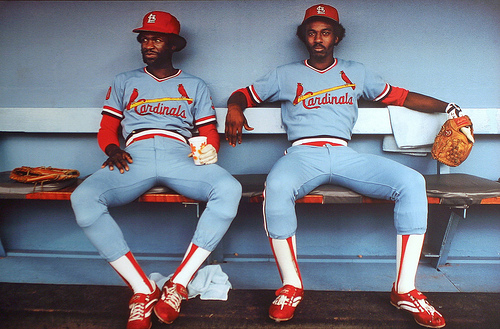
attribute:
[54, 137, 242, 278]
pants — blue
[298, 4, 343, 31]
hat — red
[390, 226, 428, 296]
red sock — white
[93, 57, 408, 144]
shirts — men's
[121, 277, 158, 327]
shoes — white, red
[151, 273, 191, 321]
shoes — white, red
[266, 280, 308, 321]
shoes — white, red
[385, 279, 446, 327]
shoes — white, red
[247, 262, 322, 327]
foot — right foot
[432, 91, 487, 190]
glove — light brown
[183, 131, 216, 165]
cup — white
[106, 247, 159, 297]
sock — red, white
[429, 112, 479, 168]
mitt — baseball mitt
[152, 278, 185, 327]
shoe — red, white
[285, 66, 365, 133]
logo — St. Louis Cardinals club's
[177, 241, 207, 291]
sock — white, red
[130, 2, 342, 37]
hats — men's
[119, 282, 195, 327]
shoes — baseball shoes, red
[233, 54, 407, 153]
jersey — baseball jersey, blue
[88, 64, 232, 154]
jersey — baseball jersey, blue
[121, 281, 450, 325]
shoes — red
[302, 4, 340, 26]
hat — red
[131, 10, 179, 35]
hat — red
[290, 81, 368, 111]
letters — red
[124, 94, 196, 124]
letters — red